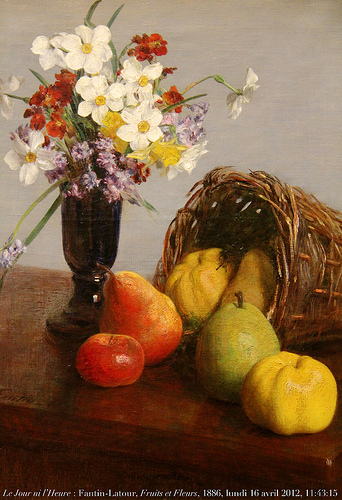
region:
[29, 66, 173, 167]
Flowers in the photo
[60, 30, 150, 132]
White flowers in the photo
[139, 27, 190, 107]
Red flowers in the photo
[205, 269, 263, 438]
Pears in the photo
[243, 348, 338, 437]
A yellow fruit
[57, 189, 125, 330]
A vase in the photo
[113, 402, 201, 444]
A table in the photo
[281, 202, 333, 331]
A basket in the photo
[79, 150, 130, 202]
A pink flower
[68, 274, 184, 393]
Orange fruit in the photo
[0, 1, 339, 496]
an image of a painting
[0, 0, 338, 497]
the painting is a still life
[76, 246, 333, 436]
a painting of fruit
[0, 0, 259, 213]
the vase has flowers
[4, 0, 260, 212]
the flowers are many colors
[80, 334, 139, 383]
the apples is red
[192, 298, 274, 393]
the pear is green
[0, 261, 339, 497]
the table is brown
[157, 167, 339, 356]
the basket is brown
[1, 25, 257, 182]
the daisies are white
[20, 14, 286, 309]
vase of flowers on a table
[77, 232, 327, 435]
fruit on a wooden table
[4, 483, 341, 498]
artist at the bottom of the artwork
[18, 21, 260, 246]
A vase of beatiful flowers in a vase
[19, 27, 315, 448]
fruit and flowers on a wooden table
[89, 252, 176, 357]
a pear on a wooden table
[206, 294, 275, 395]
green pear on a wooden table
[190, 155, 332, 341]
straw basket on a wooden table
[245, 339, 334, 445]
painted fruit of art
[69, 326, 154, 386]
painted apple on a table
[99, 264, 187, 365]
pear painted in art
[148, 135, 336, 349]
painted basket with fruit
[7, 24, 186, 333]
painted vase of flowers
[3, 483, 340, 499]
copyright of a painting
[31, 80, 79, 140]
red flowers in a vase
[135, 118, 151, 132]
yellow middle of a flower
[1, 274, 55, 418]
wooden table in a painting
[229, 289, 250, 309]
stem of a pear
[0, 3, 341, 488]
a realistic picture of flowers and fruit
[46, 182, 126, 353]
a vase color brown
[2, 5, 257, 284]
flowers in a brown vase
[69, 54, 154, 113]
white flowers in a vase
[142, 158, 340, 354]
a basket with fruits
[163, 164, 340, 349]
basket is color brown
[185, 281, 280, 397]
a pear color green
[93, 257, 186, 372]
a pear color red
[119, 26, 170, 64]
red flowers in vase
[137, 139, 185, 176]
yellow flower in a vase